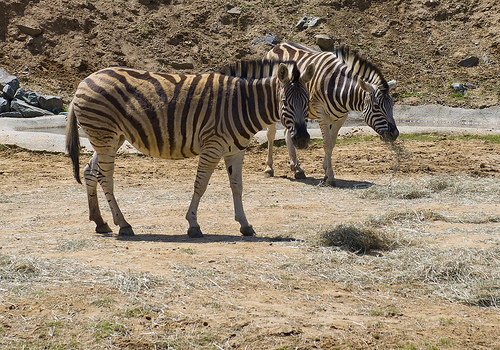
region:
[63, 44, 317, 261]
the zebra is stripe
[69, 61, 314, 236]
the zebra is dirty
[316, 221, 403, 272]
dead grass on ground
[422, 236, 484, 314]
dead grass on ground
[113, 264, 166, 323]
dead grass on ground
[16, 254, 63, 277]
dead grass on ground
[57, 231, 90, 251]
dead grass on ground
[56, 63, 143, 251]
tail laying vertical to the ground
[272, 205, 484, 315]
clumps of hay on the ground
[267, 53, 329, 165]
zebra looking at the camera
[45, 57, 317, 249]
zebra has stripes on its body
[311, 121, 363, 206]
front legs of zebra are white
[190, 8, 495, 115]
big rocks on the side of the hill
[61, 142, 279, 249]
stripes on the legs of the zebras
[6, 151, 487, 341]
dirt on the ground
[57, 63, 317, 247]
A dirty zebra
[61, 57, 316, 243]
A filthy zebra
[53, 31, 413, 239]
A pair of zebras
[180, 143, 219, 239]
Right front leg of a zebra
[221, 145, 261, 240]
Left front leg of a zebra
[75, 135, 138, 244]
The back legs of a zebra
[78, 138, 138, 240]
The hind legs of a zebra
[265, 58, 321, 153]
The head and face of a zebra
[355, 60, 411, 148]
The right side of a zebra head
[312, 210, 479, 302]
A few patches of dried grasses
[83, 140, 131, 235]
The back legs of the zebra in the front.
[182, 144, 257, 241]
The front legs of the zebra in the front.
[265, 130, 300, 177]
The back legs of the zebra in the back.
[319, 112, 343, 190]
The front legs of the zebra in the back.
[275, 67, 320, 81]
The ears of the zebra in the front.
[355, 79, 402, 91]
The ears of the zebra in the back.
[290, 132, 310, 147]
The nose of the zebra in the front.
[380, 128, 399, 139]
The nose of the zebra in the back.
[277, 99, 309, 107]
The eyes of the zebra in the front.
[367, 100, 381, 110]
The eye of the zebra in the back.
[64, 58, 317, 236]
zebra looking forward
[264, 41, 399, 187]
zebra looking at the ground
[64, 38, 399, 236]
zebras in the dirt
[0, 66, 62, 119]
pile of rocks in dirt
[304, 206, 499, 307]
pile of dry grass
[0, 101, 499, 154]
white dirt around a pond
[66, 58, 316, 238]
black and white zebra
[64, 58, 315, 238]
zebra in a habitat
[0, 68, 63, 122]
gray pile of rocks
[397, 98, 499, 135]
pond with drinking water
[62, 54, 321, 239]
a zebra with dirty hair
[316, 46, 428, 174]
zebra eating the dead grass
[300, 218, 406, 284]
dead brown grass on the ground